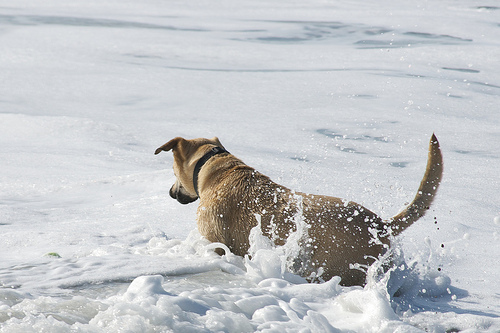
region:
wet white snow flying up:
[247, 153, 465, 312]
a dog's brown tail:
[394, 125, 453, 232]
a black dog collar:
[187, 140, 228, 195]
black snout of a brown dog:
[167, 181, 194, 206]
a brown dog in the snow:
[154, 130, 470, 288]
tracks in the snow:
[1, 2, 497, 175]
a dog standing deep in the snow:
[143, 118, 478, 293]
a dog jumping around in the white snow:
[1, 9, 498, 311]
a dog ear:
[152, 133, 183, 154]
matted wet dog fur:
[155, 134, 455, 284]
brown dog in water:
[148, 113, 463, 298]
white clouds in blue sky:
[18, 11, 66, 45]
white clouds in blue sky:
[407, 12, 464, 37]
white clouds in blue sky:
[304, 19, 348, 43]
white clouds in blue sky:
[345, 6, 377, 38]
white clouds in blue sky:
[61, 8, 103, 33]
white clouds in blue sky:
[148, 1, 203, 45]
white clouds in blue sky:
[208, 12, 245, 39]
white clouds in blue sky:
[268, 9, 296, 39]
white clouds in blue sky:
[310, 13, 362, 47]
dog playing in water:
[51, 31, 448, 332]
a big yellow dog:
[141, 90, 470, 312]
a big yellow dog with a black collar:
[135, 105, 499, 298]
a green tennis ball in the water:
[17, 110, 454, 302]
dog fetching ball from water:
[18, 134, 492, 301]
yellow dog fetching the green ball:
[32, 89, 482, 310]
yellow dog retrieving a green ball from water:
[13, 99, 483, 323]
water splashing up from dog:
[103, 217, 450, 328]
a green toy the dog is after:
[13, 195, 198, 308]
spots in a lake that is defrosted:
[92, 8, 459, 135]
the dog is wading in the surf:
[92, 94, 492, 324]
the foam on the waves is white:
[109, 212, 354, 317]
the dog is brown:
[134, 127, 498, 290]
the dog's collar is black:
[194, 146, 239, 206]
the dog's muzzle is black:
[153, 178, 201, 213]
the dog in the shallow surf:
[150, 99, 467, 281]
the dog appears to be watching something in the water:
[142, 115, 467, 312]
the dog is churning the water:
[148, 125, 458, 300]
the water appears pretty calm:
[158, 98, 353, 133]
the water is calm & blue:
[154, 18, 416, 106]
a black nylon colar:
[189, 143, 224, 196]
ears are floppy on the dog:
[154, 121, 186, 159]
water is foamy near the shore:
[1, 218, 498, 330]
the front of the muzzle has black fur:
[163, 173, 195, 213]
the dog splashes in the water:
[211, 193, 452, 325]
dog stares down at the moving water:
[138, 132, 254, 227]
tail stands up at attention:
[387, 128, 444, 242]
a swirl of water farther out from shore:
[6, 3, 479, 66]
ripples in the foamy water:
[271, 58, 498, 179]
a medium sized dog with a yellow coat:
[152, 134, 442, 278]